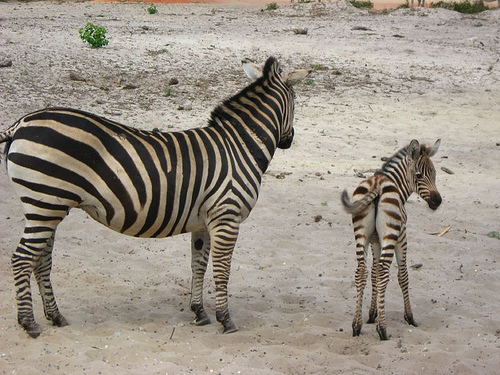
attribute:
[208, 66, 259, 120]
mane — black, white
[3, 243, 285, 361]
legs — white, black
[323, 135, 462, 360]
zebra — young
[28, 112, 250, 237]
stripes — thick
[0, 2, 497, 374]
sand — dirty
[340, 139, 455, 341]
zebra — young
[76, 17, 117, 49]
plant — small, green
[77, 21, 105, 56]
plant — green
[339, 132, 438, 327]
zebras — young, white, brown, striped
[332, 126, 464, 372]
zebra — young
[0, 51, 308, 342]
zebra — young, adult, taller, older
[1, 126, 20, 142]
tail — short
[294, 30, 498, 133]
sand — brown, tan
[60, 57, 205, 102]
rocks — small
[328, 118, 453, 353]
zebra — small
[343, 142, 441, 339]
zebra — little, baby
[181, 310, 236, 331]
feet — black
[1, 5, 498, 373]
grey sand — dry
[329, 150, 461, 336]
zebra — young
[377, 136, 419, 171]
mane — short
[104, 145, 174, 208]
strips — black, white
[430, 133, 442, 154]
ear — pointing up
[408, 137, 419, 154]
ear — pointing up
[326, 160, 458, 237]
zebra — black, white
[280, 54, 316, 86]
ear — white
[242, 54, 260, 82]
ear — white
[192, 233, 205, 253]
spot — dark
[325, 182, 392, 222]
tail — waving